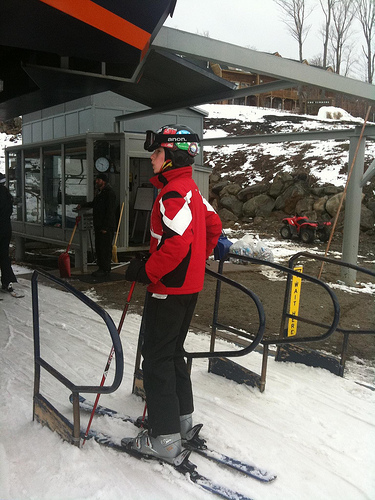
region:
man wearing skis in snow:
[33, 90, 294, 498]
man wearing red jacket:
[116, 154, 237, 293]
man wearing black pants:
[118, 271, 217, 441]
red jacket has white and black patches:
[136, 151, 221, 290]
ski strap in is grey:
[49, 352, 272, 499]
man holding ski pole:
[68, 240, 172, 447]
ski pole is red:
[75, 219, 173, 450]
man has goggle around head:
[133, 111, 202, 175]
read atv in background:
[185, 5, 365, 485]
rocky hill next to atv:
[187, 92, 373, 277]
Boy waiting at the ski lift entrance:
[118, 120, 224, 471]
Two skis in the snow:
[68, 390, 278, 498]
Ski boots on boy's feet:
[122, 409, 194, 468]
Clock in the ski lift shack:
[94, 154, 111, 174]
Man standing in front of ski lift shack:
[74, 169, 117, 278]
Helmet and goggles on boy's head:
[146, 121, 201, 159]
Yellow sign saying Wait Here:
[286, 263, 304, 336]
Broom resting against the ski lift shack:
[108, 201, 126, 264]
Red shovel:
[58, 213, 80, 277]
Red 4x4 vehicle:
[277, 210, 333, 244]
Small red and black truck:
[280, 205, 329, 243]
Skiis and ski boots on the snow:
[70, 388, 275, 498]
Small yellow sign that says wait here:
[285, 265, 305, 338]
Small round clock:
[92, 151, 112, 174]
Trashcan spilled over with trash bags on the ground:
[215, 229, 277, 264]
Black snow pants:
[142, 294, 194, 437]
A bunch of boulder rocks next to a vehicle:
[213, 171, 374, 244]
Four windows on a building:
[6, 140, 87, 231]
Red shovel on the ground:
[56, 215, 81, 287]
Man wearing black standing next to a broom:
[85, 173, 125, 281]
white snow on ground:
[315, 375, 331, 402]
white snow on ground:
[266, 392, 283, 402]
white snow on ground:
[221, 409, 237, 424]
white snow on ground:
[36, 475, 66, 491]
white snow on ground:
[128, 470, 153, 485]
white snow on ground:
[277, 416, 304, 441]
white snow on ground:
[285, 446, 301, 473]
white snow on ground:
[219, 378, 241, 397]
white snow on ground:
[23, 400, 64, 429]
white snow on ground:
[48, 447, 103, 486]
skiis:
[97, 429, 122, 447]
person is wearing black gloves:
[127, 259, 144, 283]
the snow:
[272, 414, 329, 456]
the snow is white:
[284, 389, 333, 446]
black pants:
[147, 343, 171, 408]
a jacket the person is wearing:
[151, 181, 213, 292]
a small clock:
[94, 154, 117, 172]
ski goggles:
[138, 129, 157, 147]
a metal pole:
[343, 210, 361, 260]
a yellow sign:
[293, 276, 302, 314]